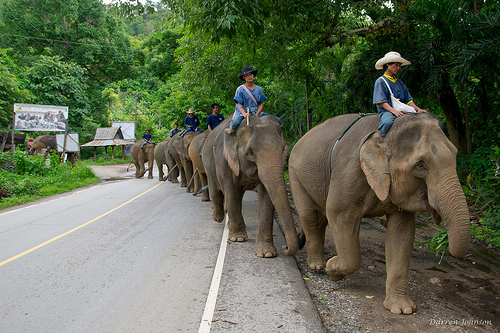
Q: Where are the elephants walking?
A: Road.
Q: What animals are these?
A: Elephants.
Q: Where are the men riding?
A: Elephants' necks.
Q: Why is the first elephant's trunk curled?
A: Carrying something with trunk.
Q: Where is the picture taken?
A: Jungle.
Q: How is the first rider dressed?
A: Blue outfit with white hat.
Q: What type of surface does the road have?
A: Asphalt.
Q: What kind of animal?
A: Elephant.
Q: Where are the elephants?
A: On the road.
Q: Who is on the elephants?
A: Group of men.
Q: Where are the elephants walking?
A: Right.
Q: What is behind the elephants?
A: Trees.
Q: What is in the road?
A: Yellow line.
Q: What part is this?
A: Forest.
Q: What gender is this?
A: Male.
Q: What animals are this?
A: Elephants.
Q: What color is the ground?
A: Grey.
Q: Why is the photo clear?
A: Its during the day.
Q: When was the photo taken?
A: Daytime.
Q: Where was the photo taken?
A: On the street.